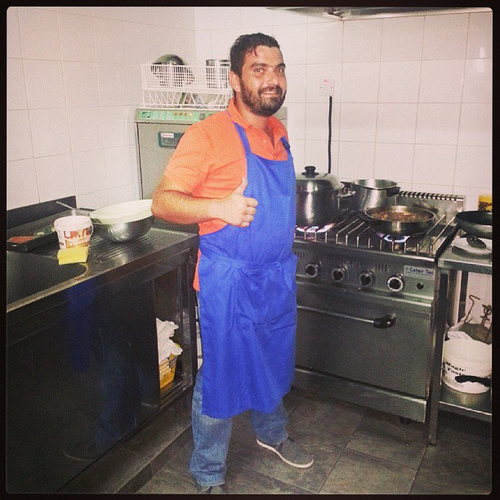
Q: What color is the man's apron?
A: Blue.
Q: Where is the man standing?
A: In a kitchen.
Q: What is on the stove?
A: Pots andpans.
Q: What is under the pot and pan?
A: Fire.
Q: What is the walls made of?
A: Tiles.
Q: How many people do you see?
A: 1 person.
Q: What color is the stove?
A: Silver.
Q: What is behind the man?
A: A mixing bowl.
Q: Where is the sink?
A: To the left and behind the man.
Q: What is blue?
A: Man's apron.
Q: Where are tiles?
A: On the wall.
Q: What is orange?
A: Shirt.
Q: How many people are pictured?
A: One.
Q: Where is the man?
A: In a kitchen.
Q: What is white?
A: Tiles on wall.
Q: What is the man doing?
A: Cooking.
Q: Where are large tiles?
A: On the floor.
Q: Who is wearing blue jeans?
A: The man.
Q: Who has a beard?
A: A man.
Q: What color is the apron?
A: Blue.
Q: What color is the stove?
A: Stainless steel.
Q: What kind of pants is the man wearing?
A: Denim.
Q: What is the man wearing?
A: A blue apron.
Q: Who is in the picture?
A: A man with brown hair.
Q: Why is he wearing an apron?
A: He's cooking.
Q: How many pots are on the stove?
A: 2.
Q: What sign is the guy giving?
A: A thumbs up.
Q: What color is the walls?
A: White.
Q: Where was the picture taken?
A: In the kitchen.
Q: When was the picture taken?
A: During the day.